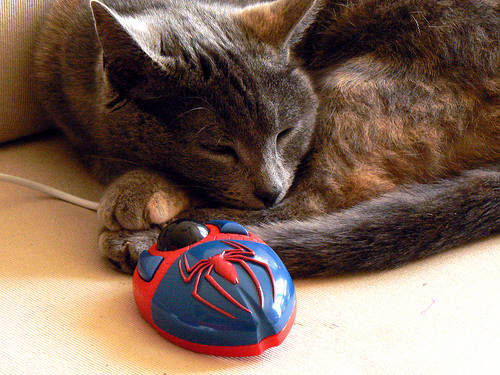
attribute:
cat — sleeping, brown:
[73, 8, 325, 225]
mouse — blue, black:
[125, 220, 296, 354]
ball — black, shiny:
[154, 218, 211, 249]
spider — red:
[177, 246, 282, 320]